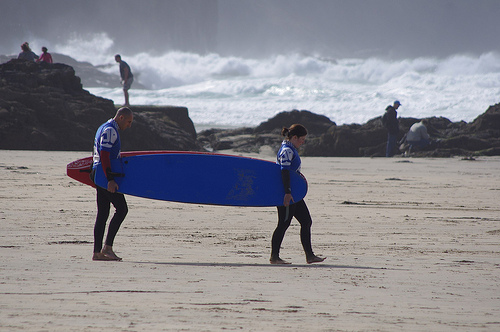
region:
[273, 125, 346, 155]
Woman has brown hair.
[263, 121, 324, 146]
Woman's hair pulled back in pony tail.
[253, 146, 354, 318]
Woman walking on sandy beach.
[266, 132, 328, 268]
Woman wearing wet suit.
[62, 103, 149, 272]
Man holding 2 surfboards.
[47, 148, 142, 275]
Man walking on sandy beach.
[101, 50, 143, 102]
Man standing on large rocks.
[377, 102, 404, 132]
Person wearing dark hoodie.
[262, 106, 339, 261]
The woman holding the surfboard.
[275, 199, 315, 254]
The black pants.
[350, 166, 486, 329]
A sandy area at the beach.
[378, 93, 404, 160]
The man with the blue hat.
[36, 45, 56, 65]
A person in a pink shirt.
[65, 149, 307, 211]
The blue and red surfboard.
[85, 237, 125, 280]
The mans feet.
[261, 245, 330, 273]
The womans feet.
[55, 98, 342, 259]
The man and woman holding a surfboard.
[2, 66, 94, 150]
A rock at the beach.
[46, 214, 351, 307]
the people are wailkimg barefoot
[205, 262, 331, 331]
the floor is coverd of asand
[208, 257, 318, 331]
the floor as many footprnints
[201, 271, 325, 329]
the floor is brown in color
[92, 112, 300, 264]
peopla re carynin the surfbord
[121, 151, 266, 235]
the surfbprd is blue in color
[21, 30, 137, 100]
people are on top of ahill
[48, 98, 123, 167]
t shirt os blue and white in color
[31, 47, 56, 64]
the blouse is pink in cilor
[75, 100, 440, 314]
two people are holding a surfboard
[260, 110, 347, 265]
the woman is walking in front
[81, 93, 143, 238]
the mani s walking behind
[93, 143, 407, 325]
the surfboard is blue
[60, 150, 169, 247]
the surfboard is red and blue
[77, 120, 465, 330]
the people are wearing matching clothes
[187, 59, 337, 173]
the waves are crashing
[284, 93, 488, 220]
rocks are by the waves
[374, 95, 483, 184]
the man is with the boy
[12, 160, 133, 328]
tracks are in the sand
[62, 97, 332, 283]
two people carrying surf board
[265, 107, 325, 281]
a woman carrying a surf board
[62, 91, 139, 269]
a man carrying a surf board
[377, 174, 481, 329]
a sandy beach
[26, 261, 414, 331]
tracks in the sand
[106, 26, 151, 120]
a man standing on a large rock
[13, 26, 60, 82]
three people on a large rock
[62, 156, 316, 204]
a red and blue surf board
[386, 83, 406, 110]
a man wearing a hat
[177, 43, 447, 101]
white waves in the ocean